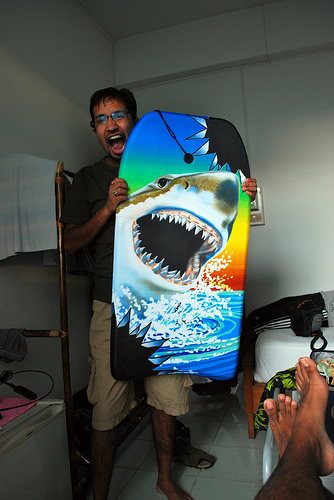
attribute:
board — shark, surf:
[94, 101, 255, 405]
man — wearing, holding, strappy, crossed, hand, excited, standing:
[45, 54, 210, 273]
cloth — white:
[25, 180, 51, 228]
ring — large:
[114, 185, 131, 202]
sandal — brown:
[177, 437, 224, 469]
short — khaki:
[75, 313, 138, 412]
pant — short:
[64, 286, 187, 436]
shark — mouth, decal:
[136, 184, 246, 298]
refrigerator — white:
[17, 402, 90, 486]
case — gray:
[222, 297, 295, 377]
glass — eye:
[90, 96, 141, 130]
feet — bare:
[249, 360, 325, 469]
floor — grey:
[221, 415, 246, 440]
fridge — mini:
[41, 431, 67, 464]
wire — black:
[31, 341, 65, 400]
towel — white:
[5, 206, 52, 242]